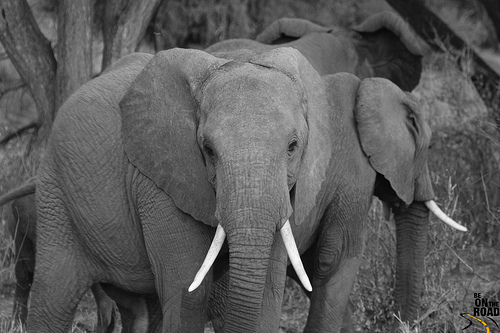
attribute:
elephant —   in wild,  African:
[306, 68, 468, 324]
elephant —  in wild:
[232, 10, 432, 94]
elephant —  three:
[257, 4, 436, 327]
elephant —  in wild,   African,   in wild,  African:
[23, 50, 325, 331]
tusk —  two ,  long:
[426, 198, 467, 232]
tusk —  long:
[377, 199, 388, 221]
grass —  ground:
[279, 117, 499, 332]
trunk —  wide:
[214, 202, 276, 331]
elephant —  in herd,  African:
[205, 11, 427, 92]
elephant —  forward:
[38, 43, 318, 328]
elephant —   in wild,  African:
[290, 71, 472, 325]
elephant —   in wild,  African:
[254, 10, 429, 90]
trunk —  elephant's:
[221, 212, 273, 332]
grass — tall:
[440, 121, 492, 302]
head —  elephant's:
[322, 27, 370, 77]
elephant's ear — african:
[256, 43, 331, 227]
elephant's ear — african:
[125, 49, 227, 228]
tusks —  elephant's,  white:
[185, 218, 314, 291]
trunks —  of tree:
[3, 0, 158, 63]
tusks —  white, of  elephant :
[188, 222, 312, 294]